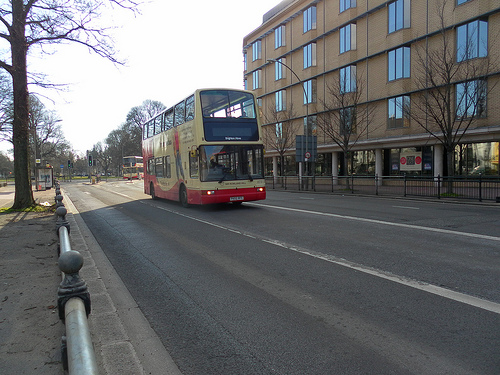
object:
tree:
[311, 69, 385, 191]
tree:
[0, 0, 142, 208]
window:
[198, 143, 266, 183]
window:
[199, 90, 260, 120]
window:
[184, 96, 196, 122]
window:
[166, 109, 178, 129]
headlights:
[205, 190, 213, 196]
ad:
[173, 125, 185, 180]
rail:
[50, 177, 98, 374]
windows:
[338, 65, 348, 94]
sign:
[296, 134, 319, 162]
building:
[242, 0, 499, 186]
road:
[67, 181, 500, 374]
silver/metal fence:
[47, 172, 104, 372]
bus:
[141, 88, 268, 207]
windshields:
[203, 144, 235, 180]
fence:
[272, 172, 499, 206]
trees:
[387, 0, 497, 196]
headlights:
[257, 186, 268, 191]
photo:
[0, 0, 499, 373]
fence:
[54, 177, 101, 374]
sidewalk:
[0, 184, 67, 373]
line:
[93, 185, 499, 315]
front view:
[200, 143, 265, 204]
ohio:
[0, 0, 499, 374]